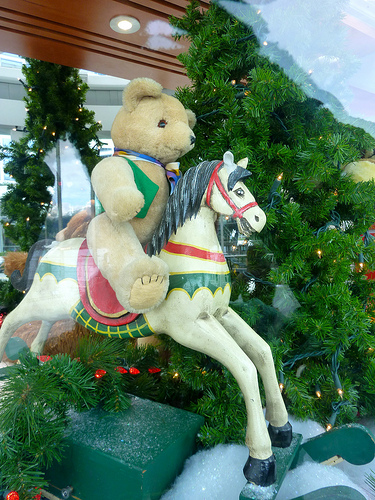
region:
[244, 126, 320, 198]
Leaves are green color.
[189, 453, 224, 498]
Snow is white color.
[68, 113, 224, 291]
Teddy bear is sitting in the horse.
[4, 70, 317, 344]
Lights are on.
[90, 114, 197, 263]
Teddy is brown color.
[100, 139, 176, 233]
Teddy is wearing green coat.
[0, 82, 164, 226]
Sunlight passes through the window.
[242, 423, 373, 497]
Cart is grern color.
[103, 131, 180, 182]
Collar around the neck.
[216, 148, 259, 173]
Two pointed ears on horse head.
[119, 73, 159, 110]
The left ear of the bear.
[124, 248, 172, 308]
The left foot of the bear.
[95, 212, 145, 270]
The left leg of the bear.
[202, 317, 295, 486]
The front legs of the horse.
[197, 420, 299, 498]
The fake snow near the horse's front legs.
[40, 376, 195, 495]
The green box beneath the horse.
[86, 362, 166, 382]
The red lights beneath the horse.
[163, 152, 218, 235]
The black mane of the horse.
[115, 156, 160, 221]
The green vest the bear is wearing.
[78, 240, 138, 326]
The red saddle on the horse's back.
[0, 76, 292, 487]
bear on rocking horse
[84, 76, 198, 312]
brown bear is stuffed animal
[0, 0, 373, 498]
holiday greenery is lighted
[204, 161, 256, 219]
rocking horse has red bridle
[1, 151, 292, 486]
rocking horse is white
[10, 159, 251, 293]
rocking horse has black mane and tail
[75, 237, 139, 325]
saddle is red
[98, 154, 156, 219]
bear wears green vest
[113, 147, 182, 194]
bear wears multi-colored scarf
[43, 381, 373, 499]
rocking horse base is green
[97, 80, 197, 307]
light brown teddy bear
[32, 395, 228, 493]
dark green wooden box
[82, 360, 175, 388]
red christmas lights on tree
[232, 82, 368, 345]
christmas tree with lights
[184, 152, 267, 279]
wooden horse head is black red and white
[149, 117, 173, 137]
brown teddy bear eyes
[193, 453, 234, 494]
fake snow under horse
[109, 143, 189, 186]
scarf around teddy bears neck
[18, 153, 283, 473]
teddy bear sitting on rocking horse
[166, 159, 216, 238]
rocking horse mane is black and white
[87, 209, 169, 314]
leg of a teddy bear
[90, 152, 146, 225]
arm of a teddy bear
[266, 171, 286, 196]
light on a christmas tree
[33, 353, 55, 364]
light on a christmas tree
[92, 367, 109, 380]
light on a christmas tree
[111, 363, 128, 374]
light on a christmas tree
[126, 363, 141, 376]
light on a christmas tree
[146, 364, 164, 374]
light on a christmas tree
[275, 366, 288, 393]
light on a christmas tree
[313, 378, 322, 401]
light on a christmas tree